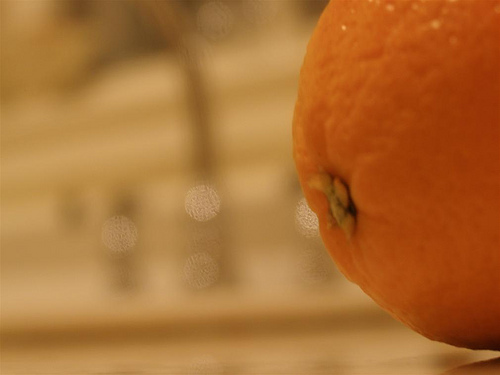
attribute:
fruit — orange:
[269, 1, 494, 372]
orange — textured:
[298, 5, 484, 302]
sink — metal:
[81, 0, 331, 312]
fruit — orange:
[291, 0, 498, 362]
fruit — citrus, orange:
[288, 3, 482, 371]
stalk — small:
[307, 173, 354, 235]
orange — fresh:
[292, 43, 460, 253]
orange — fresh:
[300, 46, 452, 248]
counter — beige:
[5, 316, 497, 371]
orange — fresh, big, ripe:
[290, 3, 498, 358]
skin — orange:
[291, 2, 496, 349]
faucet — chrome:
[57, 19, 239, 301]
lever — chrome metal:
[216, 155, 338, 293]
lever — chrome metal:
[12, 161, 152, 286]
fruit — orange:
[296, 8, 479, 267]